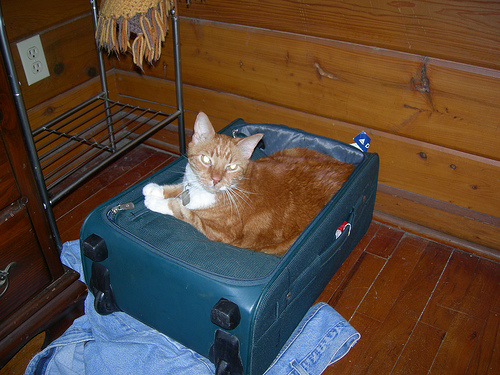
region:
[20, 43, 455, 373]
Picture of a cat.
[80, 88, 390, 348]
A blue suitcase.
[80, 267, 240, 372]
Black wheels on the suitcase.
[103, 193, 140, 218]
Zipper pull on the suitcase.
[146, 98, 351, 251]
An orange and white cat.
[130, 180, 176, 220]
White front paws on cat.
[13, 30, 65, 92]
A white electrical outlet.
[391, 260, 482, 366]
The floor is made of wood.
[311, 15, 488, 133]
The wall is made of wood.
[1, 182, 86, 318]
The edge of a dark brown drawer.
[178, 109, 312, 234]
this is a cat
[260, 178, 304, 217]
the fur is brown in color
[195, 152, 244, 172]
the eyes are bright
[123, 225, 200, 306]
this is a suitcase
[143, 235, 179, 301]
the suitcase is blue in color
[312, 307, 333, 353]
this is a cloth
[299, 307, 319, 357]
the cloth is blue in color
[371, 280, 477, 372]
this is the floor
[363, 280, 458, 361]
the floor is made of wood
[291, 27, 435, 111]
the wall is wooden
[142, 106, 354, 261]
a cat is lying in a suit case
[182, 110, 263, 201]
the cat's eyes are reflecting the camera's flash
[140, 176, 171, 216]
the kitty has white paws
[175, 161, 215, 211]
the kitty has a white chest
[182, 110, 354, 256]
the cat has orange fur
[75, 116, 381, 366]
the suitcase is blue with black wheels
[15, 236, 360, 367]
a pair of jeans are under the suit case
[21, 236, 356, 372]
the blue jeans are on the floor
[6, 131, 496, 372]
the floor and walls are wooden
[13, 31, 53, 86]
an electrical outlet is on the wall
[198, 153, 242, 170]
The glowing cat eyes.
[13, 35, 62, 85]
The white electrical outlet.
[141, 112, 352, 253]
The red furred cat.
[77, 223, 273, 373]
The blue wheeled suitcase.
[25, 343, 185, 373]
The blue jeans on the floor.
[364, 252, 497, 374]
The cherry wood flooring.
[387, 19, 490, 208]
The light wood paneled wall.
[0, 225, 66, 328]
The dark cherry wood chesser drawer.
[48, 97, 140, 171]
A black metal shelf.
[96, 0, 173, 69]
A multicolored knitted material.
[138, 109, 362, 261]
Cat is color brown and white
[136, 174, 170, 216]
Front paws of cat are white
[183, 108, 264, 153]
Ears of cat are pointy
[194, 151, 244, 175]
Eyes of cat are shiny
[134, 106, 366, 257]
Cat is in a suitcase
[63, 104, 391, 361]
Suitcase is blue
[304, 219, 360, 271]
Handle of suitcase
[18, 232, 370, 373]
Blue jeans under suitcase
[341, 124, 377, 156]
Suitcase has a blue and white tag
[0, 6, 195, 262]
Metal shelve near suitcase